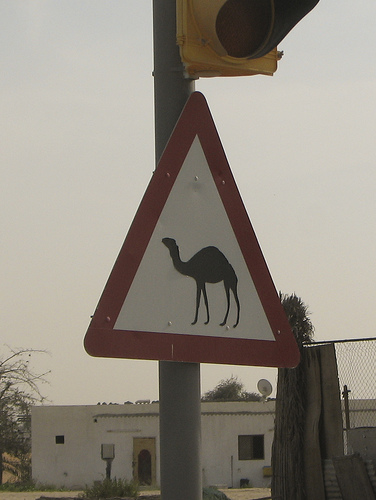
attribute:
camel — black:
[161, 235, 242, 329]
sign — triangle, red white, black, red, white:
[82, 89, 304, 372]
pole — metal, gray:
[147, 2, 206, 500]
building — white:
[29, 397, 374, 490]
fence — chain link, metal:
[272, 338, 375, 500]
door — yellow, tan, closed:
[132, 432, 159, 490]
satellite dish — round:
[257, 376, 275, 398]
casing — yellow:
[174, 2, 281, 78]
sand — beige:
[4, 489, 375, 500]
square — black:
[54, 434, 65, 447]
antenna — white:
[257, 376, 274, 400]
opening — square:
[54, 434, 68, 446]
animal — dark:
[239, 476, 251, 488]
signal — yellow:
[174, 3, 320, 79]